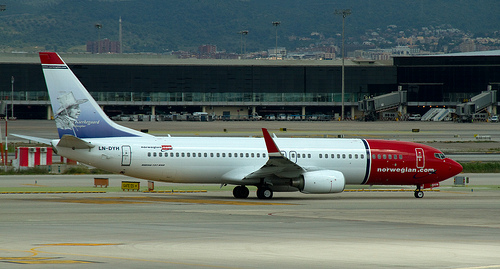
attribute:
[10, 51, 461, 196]
plane — red, white, long, parked, blue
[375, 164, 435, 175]
logo — norwegian.com, white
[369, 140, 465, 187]
front — red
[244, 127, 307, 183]
wing — white, angled up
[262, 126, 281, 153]
tip — red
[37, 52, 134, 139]
tip — red, blue, white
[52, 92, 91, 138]
portrait — woman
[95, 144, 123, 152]
letters — black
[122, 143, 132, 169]
door — white, small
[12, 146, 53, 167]
barrier — red, white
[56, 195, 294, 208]
lines — yellow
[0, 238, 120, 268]
lines — yellow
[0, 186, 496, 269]
concrete — grey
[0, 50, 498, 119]
terminal — short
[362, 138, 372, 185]
stripe — black+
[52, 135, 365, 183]
sections — white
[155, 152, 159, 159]
window — small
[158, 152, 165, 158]
window — small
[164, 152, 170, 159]
window — small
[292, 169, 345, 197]
engine — turbine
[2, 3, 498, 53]
hill — green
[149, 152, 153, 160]
window — small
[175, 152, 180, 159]
window — small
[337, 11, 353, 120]
pole — large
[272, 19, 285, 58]
pole — large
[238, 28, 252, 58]
pole — large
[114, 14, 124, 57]
pole — large